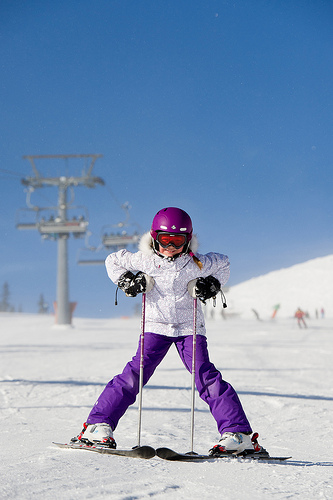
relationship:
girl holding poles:
[95, 210, 244, 416] [188, 308, 259, 355]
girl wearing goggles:
[95, 210, 244, 416] [136, 229, 189, 247]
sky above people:
[159, 24, 188, 40] [221, 293, 317, 322]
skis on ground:
[103, 438, 167, 462] [253, 482, 295, 485]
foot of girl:
[36, 412, 127, 439] [95, 210, 244, 416]